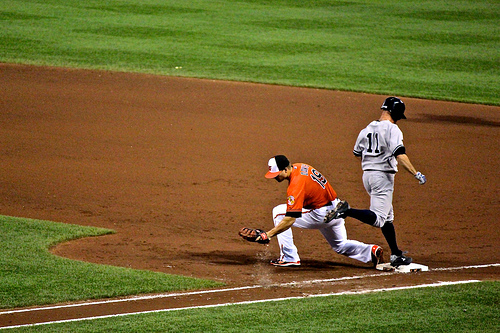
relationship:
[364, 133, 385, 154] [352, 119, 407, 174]
number on jersey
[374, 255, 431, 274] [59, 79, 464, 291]
base on field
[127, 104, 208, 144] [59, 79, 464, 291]
dirt on field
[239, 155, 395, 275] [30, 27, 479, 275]
man playing baseball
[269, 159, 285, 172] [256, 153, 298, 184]
cap on head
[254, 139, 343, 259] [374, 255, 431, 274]
man playing first base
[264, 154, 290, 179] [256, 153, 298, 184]
cap on head